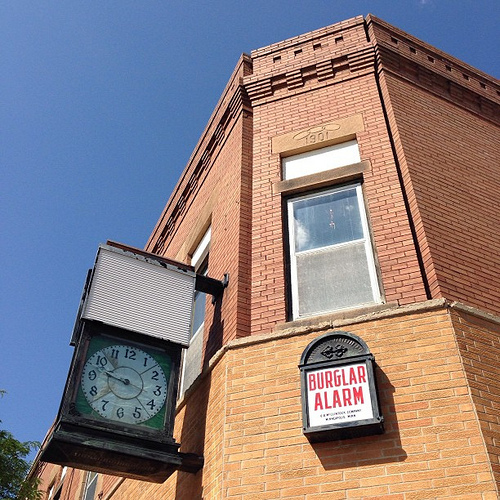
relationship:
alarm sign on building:
[296, 327, 388, 439] [159, 10, 496, 498]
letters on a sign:
[309, 364, 367, 408] [296, 357, 378, 432]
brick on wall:
[340, 461, 389, 478] [215, 13, 493, 498]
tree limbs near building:
[2, 426, 49, 497] [8, 16, 494, 497]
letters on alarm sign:
[309, 364, 367, 408] [296, 327, 388, 439]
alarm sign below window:
[296, 327, 388, 439] [284, 194, 381, 321]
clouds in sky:
[407, 0, 450, 17] [0, 0, 498, 497]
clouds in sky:
[0, 0, 149, 237] [0, 0, 498, 497]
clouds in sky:
[20, 90, 123, 165] [43, 62, 200, 159]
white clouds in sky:
[400, 0, 461, 21] [0, 0, 498, 497]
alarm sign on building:
[296, 329, 385, 445] [8, 16, 494, 497]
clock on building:
[36, 322, 191, 487] [8, 16, 494, 497]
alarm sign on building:
[296, 327, 388, 439] [8, 16, 494, 497]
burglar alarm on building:
[300, 364, 376, 434] [160, 27, 482, 381]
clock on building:
[69, 335, 172, 427] [8, 16, 494, 497]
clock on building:
[36, 322, 191, 487] [55, 93, 493, 495]